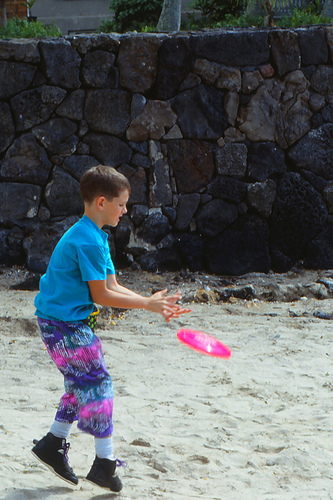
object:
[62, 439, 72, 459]
laces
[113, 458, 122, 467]
laces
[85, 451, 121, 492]
black sneakers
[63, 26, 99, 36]
window frame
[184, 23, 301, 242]
wall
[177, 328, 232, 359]
frisbee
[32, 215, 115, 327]
shirt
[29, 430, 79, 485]
shoe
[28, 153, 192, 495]
boy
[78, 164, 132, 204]
hair cut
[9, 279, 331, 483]
beach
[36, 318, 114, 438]
pants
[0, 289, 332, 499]
sand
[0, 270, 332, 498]
ground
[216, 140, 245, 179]
rock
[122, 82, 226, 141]
bricks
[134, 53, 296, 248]
structure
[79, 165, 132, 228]
head